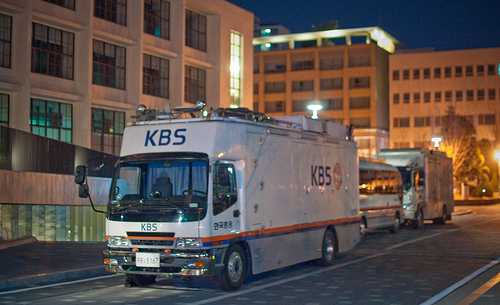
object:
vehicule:
[72, 101, 362, 292]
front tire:
[214, 243, 250, 292]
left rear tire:
[317, 228, 337, 266]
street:
[0, 202, 500, 304]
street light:
[305, 100, 326, 118]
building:
[0, 0, 255, 241]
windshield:
[107, 161, 208, 222]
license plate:
[135, 251, 161, 268]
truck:
[370, 147, 455, 230]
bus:
[359, 159, 403, 237]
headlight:
[184, 237, 203, 249]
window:
[29, 20, 76, 80]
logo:
[309, 165, 331, 187]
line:
[456, 276, 500, 305]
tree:
[430, 106, 485, 200]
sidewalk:
[0, 241, 114, 291]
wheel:
[182, 190, 206, 198]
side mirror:
[74, 165, 86, 185]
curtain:
[142, 162, 207, 198]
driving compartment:
[108, 158, 237, 215]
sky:
[229, 1, 500, 50]